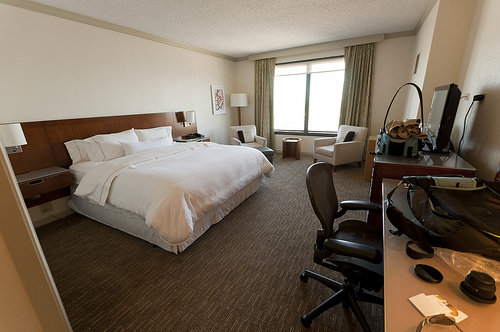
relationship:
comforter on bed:
[94, 142, 273, 243] [67, 144, 261, 255]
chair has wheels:
[299, 160, 383, 329] [297, 269, 316, 327]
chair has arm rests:
[299, 160, 383, 329] [323, 199, 381, 259]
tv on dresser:
[425, 85, 455, 151] [365, 140, 474, 224]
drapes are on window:
[253, 41, 374, 150] [271, 56, 345, 135]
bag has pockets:
[376, 80, 423, 157] [377, 134, 416, 159]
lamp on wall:
[2, 122, 30, 156] [0, 1, 236, 230]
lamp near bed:
[228, 94, 249, 130] [67, 144, 261, 255]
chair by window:
[312, 124, 366, 170] [271, 56, 345, 135]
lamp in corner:
[228, 94, 249, 130] [228, 57, 246, 136]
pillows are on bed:
[59, 127, 171, 159] [67, 144, 261, 255]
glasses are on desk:
[416, 312, 464, 331] [382, 177, 498, 331]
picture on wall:
[211, 84, 225, 116] [0, 1, 236, 230]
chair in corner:
[231, 125, 267, 146] [228, 57, 246, 136]